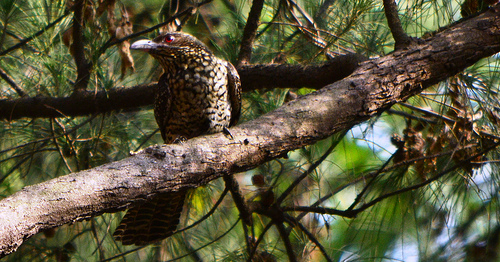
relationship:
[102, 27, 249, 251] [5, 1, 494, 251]
bird on tree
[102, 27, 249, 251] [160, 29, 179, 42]
bird has eyes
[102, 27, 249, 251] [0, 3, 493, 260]
bird on log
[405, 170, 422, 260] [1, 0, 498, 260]
pine needle on pine tree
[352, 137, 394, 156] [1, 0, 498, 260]
pine needle on pine tree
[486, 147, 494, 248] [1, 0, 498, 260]
pine needle on pine tree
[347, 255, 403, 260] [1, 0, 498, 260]
pine needle on pine tree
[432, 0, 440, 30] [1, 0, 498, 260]
pine needle on pine tree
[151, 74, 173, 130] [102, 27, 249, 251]
left wing on bird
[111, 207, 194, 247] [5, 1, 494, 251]
bird on tree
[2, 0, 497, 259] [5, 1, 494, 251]
branch on tree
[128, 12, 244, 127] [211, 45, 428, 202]
bird on branch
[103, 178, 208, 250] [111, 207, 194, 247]
tail of a bird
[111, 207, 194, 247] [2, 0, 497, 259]
bird on a branch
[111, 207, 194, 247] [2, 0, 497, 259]
bird sitting on a branch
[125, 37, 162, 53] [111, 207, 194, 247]
beak of a bird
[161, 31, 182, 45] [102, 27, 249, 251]
eye of a bird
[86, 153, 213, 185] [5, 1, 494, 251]
branches of a tree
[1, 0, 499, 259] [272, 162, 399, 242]
branches with pine needles